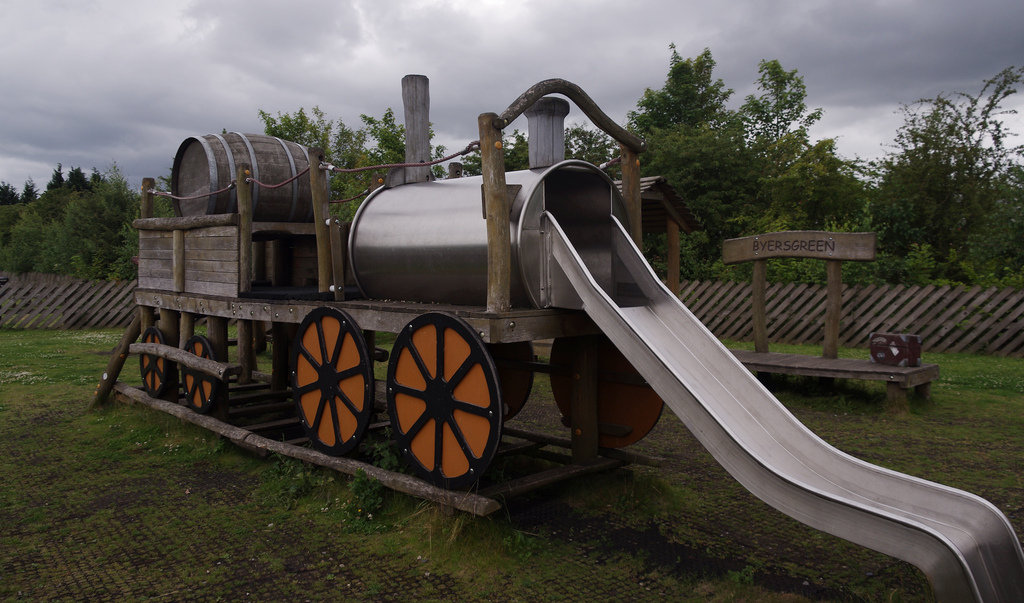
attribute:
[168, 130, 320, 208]
barrel — large, brown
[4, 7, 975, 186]
sky — overcast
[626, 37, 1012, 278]
trees — green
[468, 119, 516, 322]
pole — wooden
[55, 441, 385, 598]
grass — green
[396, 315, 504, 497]
wheel — round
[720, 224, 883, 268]
sign — wood